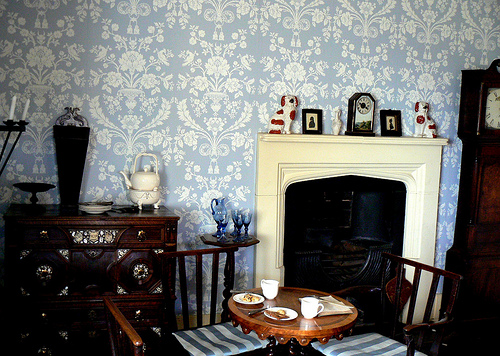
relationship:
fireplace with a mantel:
[285, 174, 405, 324] [252, 131, 449, 323]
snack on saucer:
[261, 303, 297, 323] [261, 304, 296, 324]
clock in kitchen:
[465, 52, 496, 132] [0, 0, 500, 356]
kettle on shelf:
[118, 151, 164, 212] [7, 193, 184, 242]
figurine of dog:
[414, 100, 437, 138] [268, 95, 300, 132]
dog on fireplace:
[268, 95, 300, 132] [285, 170, 405, 325]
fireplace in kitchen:
[285, 170, 405, 325] [54, 46, 475, 339]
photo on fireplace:
[293, 103, 331, 143] [276, 171, 420, 306]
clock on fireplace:
[342, 85, 374, 136] [285, 170, 405, 325]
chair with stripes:
[314, 246, 464, 354] [308, 333, 420, 354]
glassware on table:
[208, 187, 258, 256] [166, 217, 263, 341]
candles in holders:
[8, 95, 31, 120] [1, 117, 28, 172]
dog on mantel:
[268, 95, 300, 134] [252, 131, 449, 323]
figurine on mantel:
[412, 100, 439, 137] [252, 131, 449, 323]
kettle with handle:
[118, 151, 164, 212] [131, 145, 163, 173]